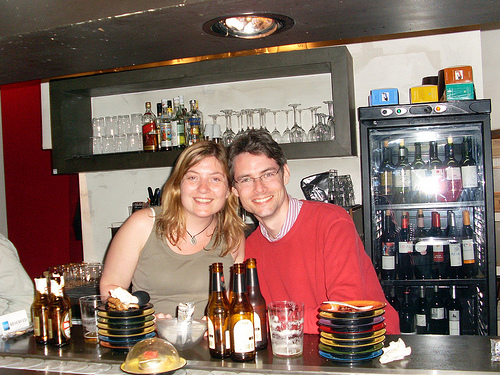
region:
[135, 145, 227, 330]
woman standing behind bar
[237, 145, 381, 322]
man standing behind bar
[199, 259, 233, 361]
beer bottle on counter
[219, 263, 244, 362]
beer bottle on counter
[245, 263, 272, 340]
beer bottle on counter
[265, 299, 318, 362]
clear glass on counter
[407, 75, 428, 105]
yellow box on cooler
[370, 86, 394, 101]
blue box on cooler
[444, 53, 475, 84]
red box on cooler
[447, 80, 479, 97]
green box on cooler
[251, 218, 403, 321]
the shirt is red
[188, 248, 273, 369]
thrre bottles of beer are on the table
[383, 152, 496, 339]
wine bottles are in the fridge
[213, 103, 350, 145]
the glasses are upside down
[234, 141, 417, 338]
the man has glasses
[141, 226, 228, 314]
the vest is brown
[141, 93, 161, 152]
johny walker is on the shelf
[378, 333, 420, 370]
tissue is on the table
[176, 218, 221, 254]
necklace is around her neck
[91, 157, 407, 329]
the two people are close together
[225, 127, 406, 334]
A man wearing a red shirt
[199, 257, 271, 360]
Bottles on the counter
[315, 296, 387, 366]
A colorful stack of plates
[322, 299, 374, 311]
A plastic spoon on the plates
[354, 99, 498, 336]
A tall black wine cooler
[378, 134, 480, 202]
Bottles of wine on the shelf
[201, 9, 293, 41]
A round light in the ceiling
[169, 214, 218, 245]
A necklace on a woman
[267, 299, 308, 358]
An empty beer glass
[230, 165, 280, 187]
Glasses on the man's face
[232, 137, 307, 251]
this is a man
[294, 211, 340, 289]
this is a sweater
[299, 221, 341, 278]
the sweater is red in color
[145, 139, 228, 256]
this is a lady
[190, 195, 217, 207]
the lady is smiling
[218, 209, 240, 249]
this is the hair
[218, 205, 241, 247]
the hair is long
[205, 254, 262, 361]
these are the bottles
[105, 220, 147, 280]
this is the hand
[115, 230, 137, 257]
the lady is light skinned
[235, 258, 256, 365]
bottle on the table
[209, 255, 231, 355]
bottle on the table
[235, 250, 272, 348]
bottle on the table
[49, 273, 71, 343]
bottle on the table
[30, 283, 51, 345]
bottle on the table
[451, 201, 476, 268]
wine bottle on cooler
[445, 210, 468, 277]
wine bottle on cooler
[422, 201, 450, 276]
wine bottle on cooler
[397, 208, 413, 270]
wine bottle on cooler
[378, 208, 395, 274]
wine bottle on cooler